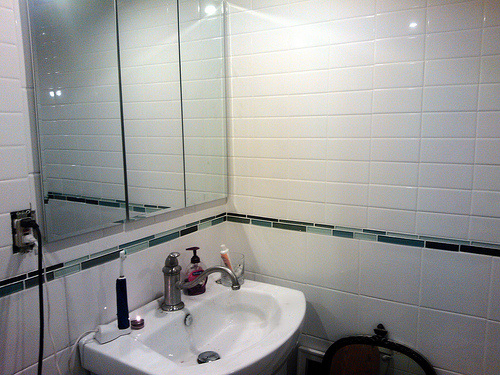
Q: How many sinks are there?
A: 1.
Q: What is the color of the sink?
A: White.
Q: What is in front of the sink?
A: Mirror.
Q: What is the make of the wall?
A: Tiles.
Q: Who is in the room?
A: No one.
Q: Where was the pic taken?
A: In a bathroom.